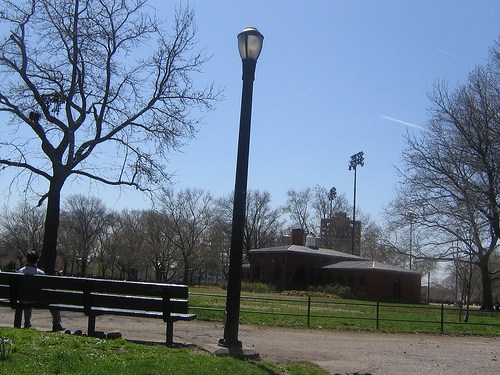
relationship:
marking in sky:
[380, 115, 437, 137] [3, 2, 492, 268]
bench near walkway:
[1, 271, 194, 343] [64, 307, 484, 367]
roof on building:
[253, 234, 364, 260] [249, 228, 371, 291]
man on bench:
[16, 249, 68, 331] [1, 253, 200, 353]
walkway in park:
[0, 301, 497, 372] [0, 217, 497, 372]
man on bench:
[16, 249, 68, 331] [1, 265, 201, 347]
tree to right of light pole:
[373, 45, 498, 314] [215, 17, 266, 349]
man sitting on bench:
[16, 249, 44, 280] [0, 271, 195, 325]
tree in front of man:
[1, 2, 171, 274] [17, 245, 62, 340]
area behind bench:
[0, 324, 325, 372] [1, 265, 201, 347]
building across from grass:
[227, 242, 426, 302] [257, 292, 328, 318]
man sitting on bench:
[16, 249, 68, 331] [0, 267, 197, 357]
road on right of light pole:
[62, 327, 497, 373] [220, 25, 267, 350]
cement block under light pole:
[196, 341, 267, 363] [215, 61, 256, 348]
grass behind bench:
[9, 350, 219, 374] [1, 265, 201, 347]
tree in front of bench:
[0, 0, 226, 275] [1, 271, 194, 343]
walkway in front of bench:
[0, 301, 497, 372] [1, 265, 201, 347]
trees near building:
[6, 26, 218, 292] [246, 222, 426, 312]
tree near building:
[373, 45, 498, 314] [246, 222, 426, 312]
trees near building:
[0, 187, 228, 272] [246, 222, 426, 312]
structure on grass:
[242, 227, 423, 304] [189, 285, 499, 337]